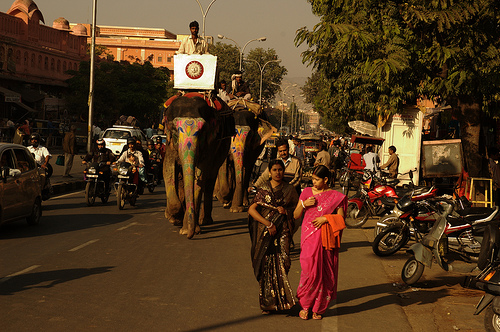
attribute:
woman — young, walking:
[296, 162, 346, 323]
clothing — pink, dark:
[296, 186, 347, 312]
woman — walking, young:
[247, 159, 303, 317]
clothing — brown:
[250, 179, 301, 310]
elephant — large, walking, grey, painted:
[162, 90, 237, 241]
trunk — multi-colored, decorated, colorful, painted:
[171, 117, 206, 238]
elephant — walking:
[214, 101, 265, 215]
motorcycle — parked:
[399, 202, 498, 285]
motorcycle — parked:
[372, 188, 489, 259]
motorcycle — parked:
[341, 176, 442, 227]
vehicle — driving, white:
[0, 141, 53, 234]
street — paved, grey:
[1, 164, 499, 330]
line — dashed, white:
[1, 205, 168, 285]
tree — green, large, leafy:
[294, 1, 499, 140]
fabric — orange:
[321, 213, 347, 253]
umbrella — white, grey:
[346, 120, 377, 138]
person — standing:
[379, 142, 400, 182]